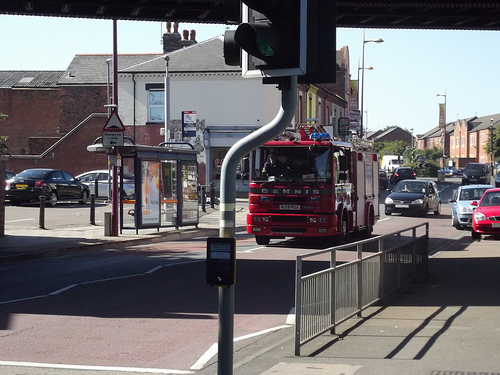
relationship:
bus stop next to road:
[88, 134, 200, 233] [3, 189, 494, 371]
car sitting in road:
[5, 167, 90, 208] [6, 190, 135, 255]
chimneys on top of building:
[161, 17, 206, 54] [0, 20, 227, 182]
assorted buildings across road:
[0, 43, 365, 194] [3, 189, 494, 371]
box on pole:
[201, 234, 236, 290] [212, 77, 303, 367]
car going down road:
[469, 181, 498, 242] [3, 189, 494, 371]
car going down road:
[448, 184, 497, 231] [3, 189, 494, 371]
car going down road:
[381, 170, 448, 225] [3, 189, 494, 371]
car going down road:
[5, 160, 96, 211] [3, 189, 494, 371]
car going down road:
[71, 160, 141, 206] [3, 189, 494, 371]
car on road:
[382, 179, 442, 216] [3, 189, 494, 371]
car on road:
[469, 187, 500, 242] [3, 189, 494, 371]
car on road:
[446, 182, 497, 228] [3, 189, 494, 371]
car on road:
[391, 165, 420, 186] [3, 189, 494, 371]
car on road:
[458, 159, 491, 184] [3, 189, 494, 371]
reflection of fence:
[299, 264, 469, 364] [292, 220, 430, 357]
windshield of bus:
[247, 146, 332, 183] [243, 133, 382, 245]